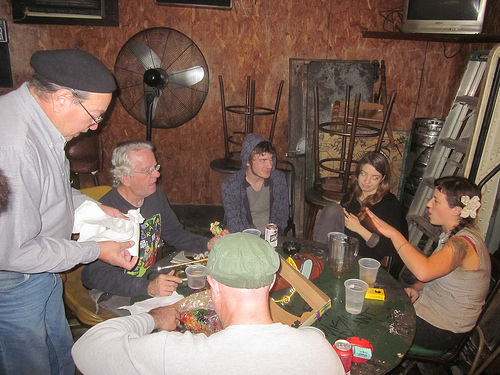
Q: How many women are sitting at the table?
A: Two.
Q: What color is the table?
A: Green.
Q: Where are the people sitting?
A: At a table.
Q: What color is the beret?
A: Black.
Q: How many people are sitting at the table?
A: Five.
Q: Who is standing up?
A: The man with the beret.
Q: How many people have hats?
A: Two.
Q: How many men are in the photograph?
A: Three.